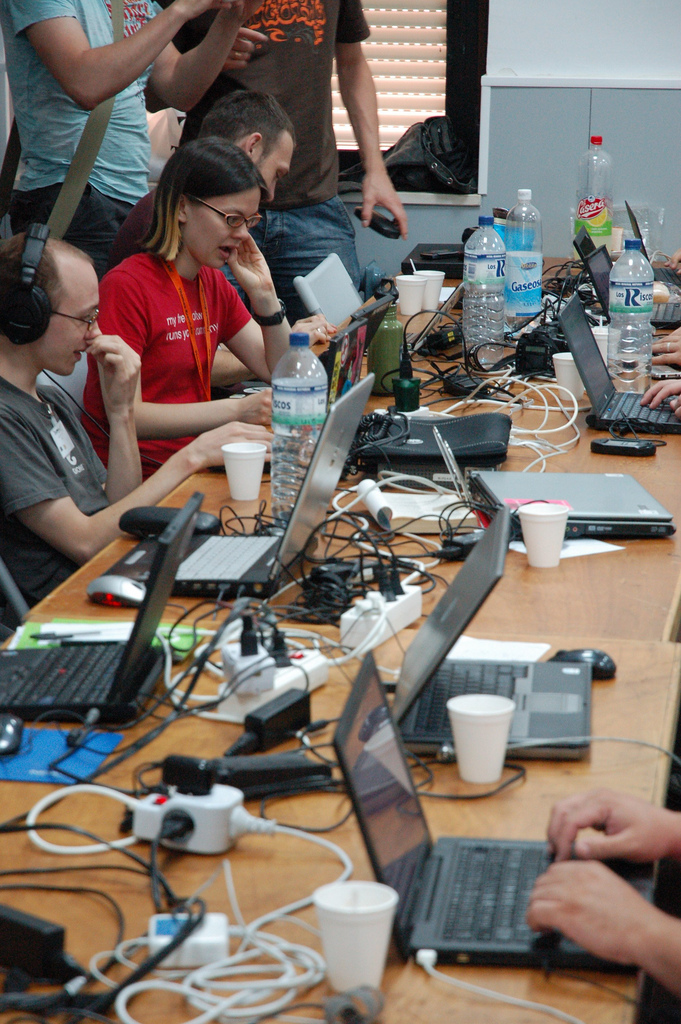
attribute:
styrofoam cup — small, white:
[311, 877, 398, 995]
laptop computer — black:
[387, 504, 595, 754]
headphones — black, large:
[4, 226, 58, 338]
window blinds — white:
[324, 4, 443, 153]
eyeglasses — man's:
[49, 307, 100, 329]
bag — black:
[337, 116, 476, 194]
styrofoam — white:
[444, 693, 514, 783]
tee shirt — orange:
[82, 248, 252, 481]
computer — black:
[329, 651, 655, 977]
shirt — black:
[146, 1, 370, 212]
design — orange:
[245, 3, 325, 49]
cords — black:
[275, 510, 453, 623]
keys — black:
[439, 843, 547, 945]